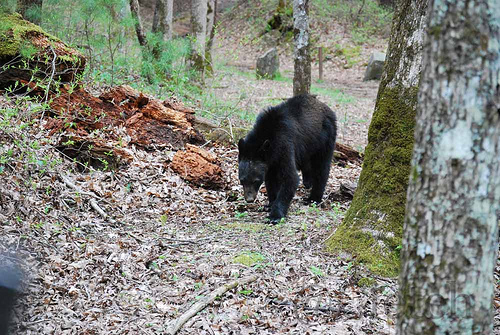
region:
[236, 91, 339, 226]
wild adult black bear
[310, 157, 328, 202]
bear leg covered in black fur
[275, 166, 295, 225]
bear leg covered in black fur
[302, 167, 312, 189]
bear leg covered in black fur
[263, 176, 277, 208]
bear leg covered in black fur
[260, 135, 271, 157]
furry black bear ear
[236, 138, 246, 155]
furry black bear ear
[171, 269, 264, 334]
long light brown stick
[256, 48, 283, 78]
large grey colored rock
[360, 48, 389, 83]
large grey colored rock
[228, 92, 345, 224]
the bear is walking in the woods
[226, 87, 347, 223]
the bear is black in color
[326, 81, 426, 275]
the moss is growing on the side of the tree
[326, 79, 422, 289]
the moss on the tree is green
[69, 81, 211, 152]
a tree is rotten on the ground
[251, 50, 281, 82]
a tree stump in the back ground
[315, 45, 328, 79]
a fence post in the back ground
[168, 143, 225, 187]
another piece of rotten wood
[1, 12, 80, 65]
moss growing on the tree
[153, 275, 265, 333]
a stick on the ground in front of the bear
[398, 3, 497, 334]
A trunk of a tree.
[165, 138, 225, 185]
A brown piece of dead tree.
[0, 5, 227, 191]
A dead tree on the ground.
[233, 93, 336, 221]
A dark colored animal.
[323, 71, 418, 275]
Green moss on a trunk of a tree.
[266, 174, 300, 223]
Front legs of a dark-colored animal.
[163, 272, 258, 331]
A dead brunch on the ground.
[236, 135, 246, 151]
A ear of an animal.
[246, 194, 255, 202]
A nose of an animal.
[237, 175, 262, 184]
Eyes of an animal.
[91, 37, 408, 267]
a bear in the woods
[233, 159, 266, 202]
the head of a bear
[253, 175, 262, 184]
the eye of a bear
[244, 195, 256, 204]
the nose on a bear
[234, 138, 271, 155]
the ears on a bear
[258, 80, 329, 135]
the back of a bear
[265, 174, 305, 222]
the front legs of a bear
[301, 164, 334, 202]
the rear legs of a bear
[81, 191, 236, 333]
grass, leaves, and sticks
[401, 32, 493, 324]
the trunk of a tree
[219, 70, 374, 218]
A bear in the forest.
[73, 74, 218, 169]
Wood on the ground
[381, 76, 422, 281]
Vines growing on the tree.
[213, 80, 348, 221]
A black bear walking.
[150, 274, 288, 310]
A branch on the ground.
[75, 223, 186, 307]
Dead leaves on the ground.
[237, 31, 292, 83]
A tree trunk in forest.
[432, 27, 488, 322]
The tree trunk is old.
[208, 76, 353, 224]
Bear looking for food.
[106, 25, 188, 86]
Trees in the forest.